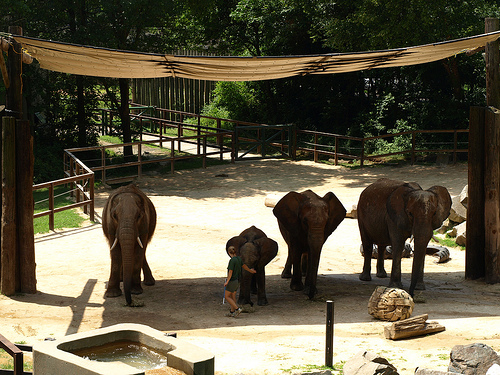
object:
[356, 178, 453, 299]
elephant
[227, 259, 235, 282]
arm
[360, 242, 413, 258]
tire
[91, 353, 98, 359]
water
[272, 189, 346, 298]
elephant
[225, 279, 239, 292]
shorts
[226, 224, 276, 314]
elephant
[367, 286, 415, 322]
wood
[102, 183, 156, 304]
elephants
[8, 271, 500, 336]
shade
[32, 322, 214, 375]
container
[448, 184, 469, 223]
rocks elephant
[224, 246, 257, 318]
man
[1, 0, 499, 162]
trees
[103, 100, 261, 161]
fence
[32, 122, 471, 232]
fence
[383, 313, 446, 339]
log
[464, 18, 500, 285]
pole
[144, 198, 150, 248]
ear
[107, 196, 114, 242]
ear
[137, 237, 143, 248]
tusk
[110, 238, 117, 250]
tusk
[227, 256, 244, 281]
shirt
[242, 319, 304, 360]
floor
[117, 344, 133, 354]
water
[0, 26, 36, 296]
pole/gathers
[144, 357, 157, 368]
water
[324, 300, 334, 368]
pole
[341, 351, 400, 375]
rock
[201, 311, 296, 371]
ground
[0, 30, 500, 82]
canopy roof